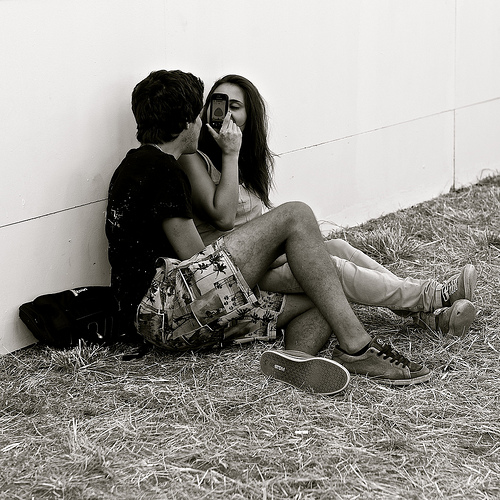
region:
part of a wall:
[298, 35, 373, 84]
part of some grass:
[211, 392, 261, 447]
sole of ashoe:
[296, 364, 331, 391]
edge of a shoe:
[328, 347, 351, 404]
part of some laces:
[377, 344, 409, 379]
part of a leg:
[315, 275, 345, 330]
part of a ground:
[109, 460, 141, 494]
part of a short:
[223, 292, 260, 320]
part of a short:
[194, 281, 235, 318]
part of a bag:
[73, 282, 118, 317]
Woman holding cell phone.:
[201, 89, 266, 167]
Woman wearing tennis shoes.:
[446, 256, 488, 331]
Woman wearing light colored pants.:
[374, 252, 428, 326]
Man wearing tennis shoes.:
[341, 338, 438, 416]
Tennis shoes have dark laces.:
[380, 329, 437, 399]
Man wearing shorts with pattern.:
[168, 271, 248, 411]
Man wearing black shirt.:
[95, 170, 187, 328]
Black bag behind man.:
[36, 295, 156, 371]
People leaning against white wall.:
[26, 176, 126, 328]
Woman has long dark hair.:
[217, 68, 294, 213]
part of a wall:
[354, 42, 404, 89]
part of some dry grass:
[229, 423, 286, 474]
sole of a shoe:
[301, 360, 328, 387]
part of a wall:
[0, 317, 33, 345]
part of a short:
[181, 297, 225, 354]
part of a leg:
[338, 331, 359, 354]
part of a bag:
[80, 300, 117, 333]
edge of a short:
[261, 281, 288, 314]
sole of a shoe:
[454, 304, 469, 321]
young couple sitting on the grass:
[96, 53, 466, 414]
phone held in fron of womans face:
[209, 88, 233, 134]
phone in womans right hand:
[205, 87, 236, 134]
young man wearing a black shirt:
[96, 129, 191, 352]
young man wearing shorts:
[125, 241, 285, 353]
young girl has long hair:
[210, 70, 273, 207]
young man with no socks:
[255, 313, 439, 408]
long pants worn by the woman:
[315, 221, 482, 339]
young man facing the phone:
[124, 65, 209, 162]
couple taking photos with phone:
[88, 41, 465, 425]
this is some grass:
[77, 387, 267, 492]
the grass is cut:
[71, 392, 206, 487]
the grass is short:
[79, 393, 206, 475]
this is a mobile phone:
[208, 94, 227, 121]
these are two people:
[98, 70, 453, 349]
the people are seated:
[111, 70, 461, 395]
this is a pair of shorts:
[170, 262, 265, 331]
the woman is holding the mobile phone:
[208, 96, 246, 244]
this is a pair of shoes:
[258, 344, 445, 396]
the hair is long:
[247, 107, 274, 177]